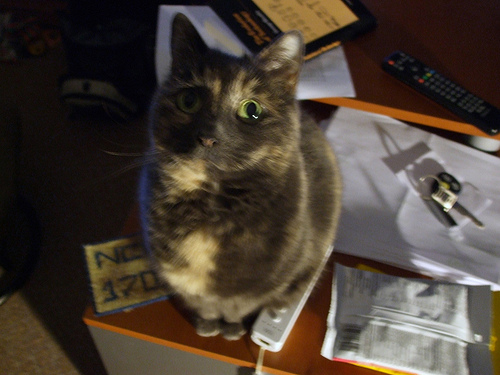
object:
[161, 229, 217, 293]
white chest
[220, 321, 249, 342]
paw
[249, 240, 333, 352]
controller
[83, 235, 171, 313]
sign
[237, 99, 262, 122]
eye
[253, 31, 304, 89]
ear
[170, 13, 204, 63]
ear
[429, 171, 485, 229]
keys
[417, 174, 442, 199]
key chain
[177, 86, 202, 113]
eye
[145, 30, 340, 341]
cat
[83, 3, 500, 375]
desk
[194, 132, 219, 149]
nose